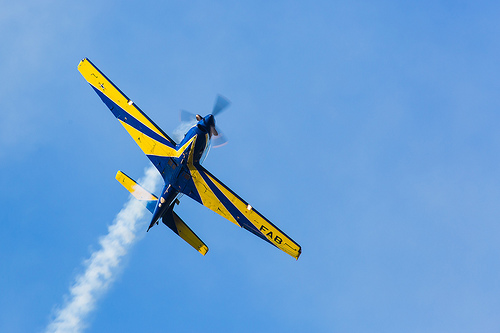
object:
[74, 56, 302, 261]
plane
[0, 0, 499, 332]
clouds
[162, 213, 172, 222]
blue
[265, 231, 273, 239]
black letter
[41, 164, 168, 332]
smoke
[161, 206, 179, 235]
stripe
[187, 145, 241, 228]
stripe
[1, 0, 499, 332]
sky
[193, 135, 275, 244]
stripe